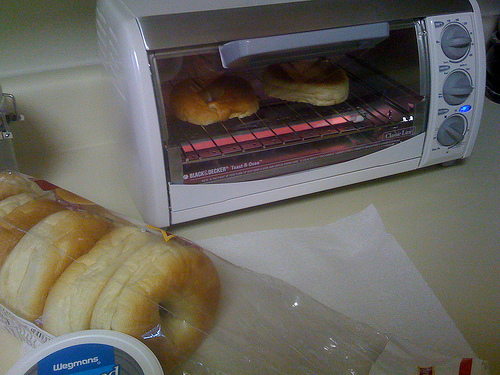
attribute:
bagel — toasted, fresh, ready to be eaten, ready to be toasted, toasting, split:
[162, 62, 265, 137]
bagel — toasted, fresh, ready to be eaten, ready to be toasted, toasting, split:
[257, 49, 354, 115]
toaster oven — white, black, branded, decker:
[90, 1, 493, 236]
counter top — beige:
[3, 77, 497, 372]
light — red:
[177, 108, 394, 159]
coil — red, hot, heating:
[169, 108, 406, 167]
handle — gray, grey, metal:
[207, 16, 405, 64]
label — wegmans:
[16, 339, 156, 374]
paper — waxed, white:
[139, 187, 495, 373]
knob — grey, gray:
[433, 20, 479, 62]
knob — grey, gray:
[437, 68, 474, 106]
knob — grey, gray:
[433, 110, 469, 150]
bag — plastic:
[0, 169, 403, 375]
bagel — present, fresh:
[92, 231, 239, 364]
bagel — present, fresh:
[37, 218, 168, 345]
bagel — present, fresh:
[0, 205, 117, 322]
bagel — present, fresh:
[0, 181, 69, 250]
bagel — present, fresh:
[0, 166, 35, 196]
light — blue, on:
[458, 101, 472, 115]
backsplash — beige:
[1, 2, 499, 75]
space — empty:
[220, 256, 394, 374]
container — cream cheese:
[5, 326, 167, 374]